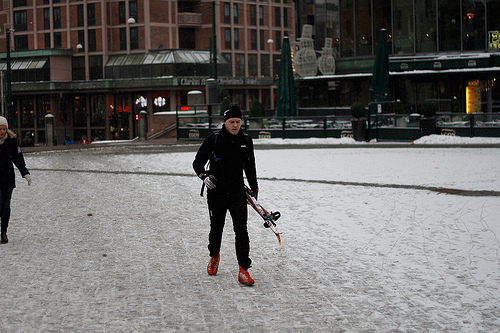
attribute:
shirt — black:
[195, 129, 267, 203]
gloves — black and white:
[195, 174, 210, 191]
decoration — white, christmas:
[293, 26, 318, 76]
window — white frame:
[222, 26, 232, 51]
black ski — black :
[242, 185, 286, 247]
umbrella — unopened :
[267, 31, 303, 136]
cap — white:
[1, 112, 10, 130]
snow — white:
[316, 147, 490, 182]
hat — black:
[220, 104, 245, 119]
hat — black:
[210, 101, 235, 125]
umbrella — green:
[369, 21, 394, 99]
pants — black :
[205, 189, 252, 269]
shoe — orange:
[205, 252, 221, 274]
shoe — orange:
[236, 263, 254, 286]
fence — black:
[281, 103, 340, 130]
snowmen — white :
[293, 18, 336, 77]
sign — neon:
[176, 102, 211, 114]